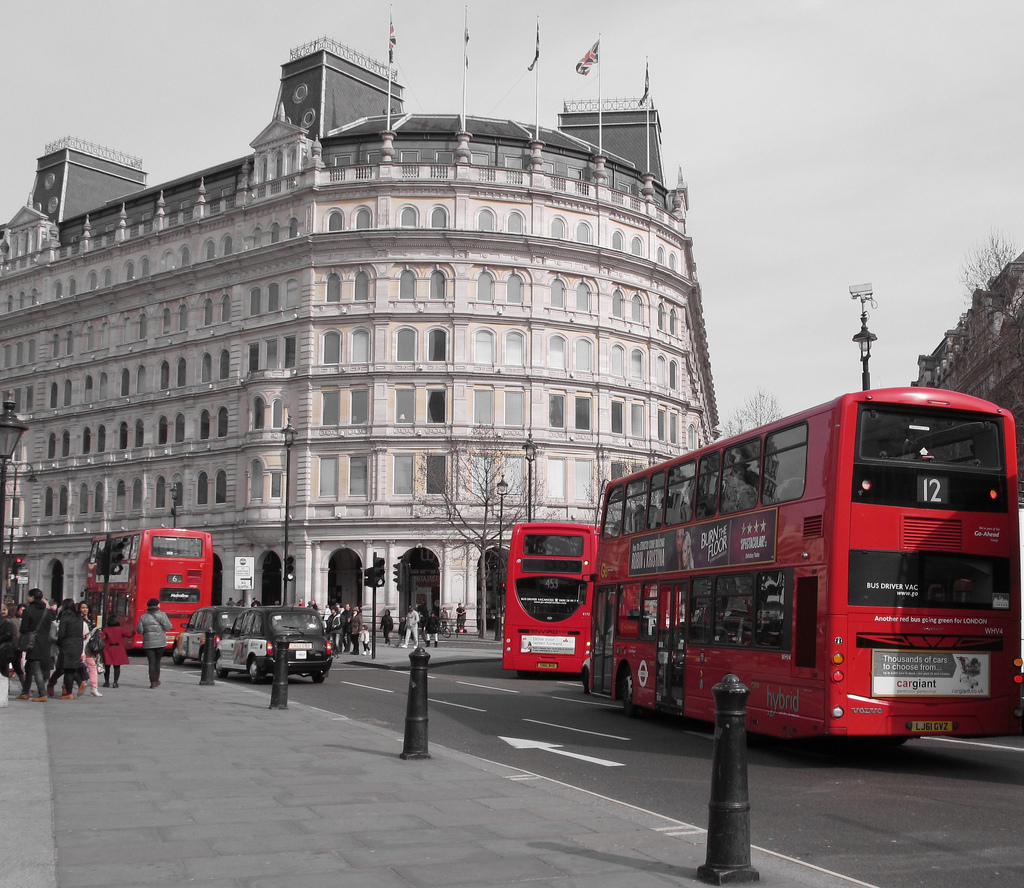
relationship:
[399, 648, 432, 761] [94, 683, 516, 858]
pillars on sidewalk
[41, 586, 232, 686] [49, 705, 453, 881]
people on sidewalk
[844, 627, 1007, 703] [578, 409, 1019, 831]
sign on bus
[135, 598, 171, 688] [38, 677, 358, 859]
people on sidewalk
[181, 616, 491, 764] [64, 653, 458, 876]
pillars on sidewalk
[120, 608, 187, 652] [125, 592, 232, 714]
jacket on person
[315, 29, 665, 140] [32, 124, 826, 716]
poles on building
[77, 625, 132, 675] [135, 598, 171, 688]
coat on people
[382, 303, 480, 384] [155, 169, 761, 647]
window on building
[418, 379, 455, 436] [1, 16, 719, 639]
window on building